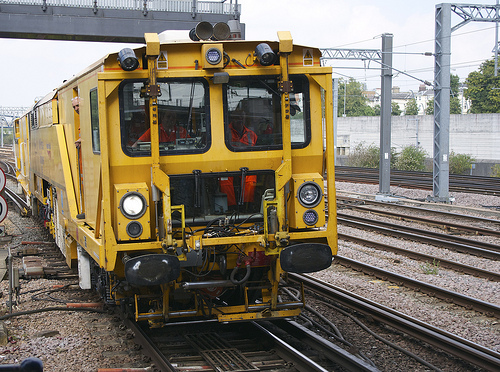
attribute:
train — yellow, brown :
[7, 14, 349, 336]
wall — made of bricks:
[344, 116, 499, 166]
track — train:
[223, 136, 493, 366]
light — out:
[295, 180, 323, 205]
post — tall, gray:
[428, 2, 453, 200]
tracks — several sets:
[339, 191, 499, 361]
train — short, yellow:
[90, 42, 346, 287]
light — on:
[121, 191, 145, 215]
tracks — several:
[53, 123, 488, 336]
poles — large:
[380, 91, 444, 205]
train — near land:
[13, 22, 337, 323]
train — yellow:
[35, 60, 409, 293]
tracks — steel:
[119, 271, 496, 368]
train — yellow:
[12, 32, 377, 355]